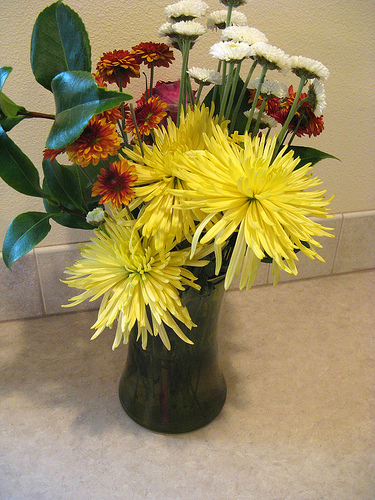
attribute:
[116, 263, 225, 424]
vase — glass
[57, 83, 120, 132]
leaf — green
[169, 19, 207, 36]
flower — white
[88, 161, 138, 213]
flower — orange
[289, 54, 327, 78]
flower — white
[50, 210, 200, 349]
petals — red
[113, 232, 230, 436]
vase — transparent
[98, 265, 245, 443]
vase — clear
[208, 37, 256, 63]
flower — white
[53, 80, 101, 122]
leaves — Green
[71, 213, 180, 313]
flower — is yellow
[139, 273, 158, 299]
petal — is long, is thin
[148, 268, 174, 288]
petal — is long, is thin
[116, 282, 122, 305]
petal — is long, is thin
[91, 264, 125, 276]
petal — is long, is thin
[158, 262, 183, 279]
petal — is long, is thin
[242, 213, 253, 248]
petal — yellow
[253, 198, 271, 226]
petal — yellow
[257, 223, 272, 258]
petal — yellow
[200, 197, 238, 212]
petal — yellow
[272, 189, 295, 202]
petal — yellow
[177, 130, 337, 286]
flower — yellow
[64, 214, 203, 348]
flower — yellow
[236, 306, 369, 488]
floor — granite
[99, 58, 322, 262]
flower — yellow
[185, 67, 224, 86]
flower — small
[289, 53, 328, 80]
flower — small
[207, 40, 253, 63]
flower — small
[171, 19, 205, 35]
flower — small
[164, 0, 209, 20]
flower — small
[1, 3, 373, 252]
wall — painted, white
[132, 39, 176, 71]
flower — red and orange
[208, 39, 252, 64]
flower — white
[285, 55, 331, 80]
flower — white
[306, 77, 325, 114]
flower — white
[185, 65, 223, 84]
flower — white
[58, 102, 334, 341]
flower — yellow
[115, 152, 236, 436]
vase — green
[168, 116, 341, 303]
flower — yellow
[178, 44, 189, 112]
stem — long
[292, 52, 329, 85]
flower — white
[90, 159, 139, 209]
flower — red, orange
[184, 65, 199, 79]
petal — yellow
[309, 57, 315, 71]
petal — yellow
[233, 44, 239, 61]
petal — yellow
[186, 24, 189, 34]
petal — yellow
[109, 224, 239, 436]
flower — white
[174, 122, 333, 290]
flower — yellow, large